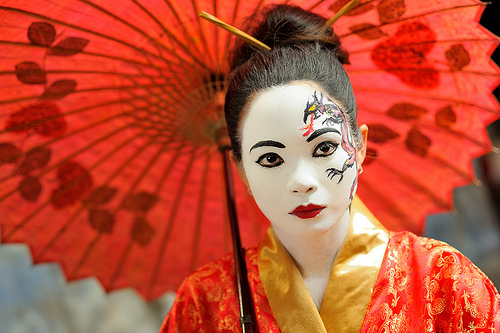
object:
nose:
[283, 152, 318, 199]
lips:
[283, 201, 344, 233]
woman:
[188, 3, 438, 285]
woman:
[159, 3, 499, 331]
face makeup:
[239, 75, 359, 245]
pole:
[221, 159, 250, 321]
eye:
[252, 150, 288, 170]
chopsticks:
[199, 0, 357, 52]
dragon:
[287, 89, 379, 211]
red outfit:
[159, 228, 497, 330]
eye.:
[309, 137, 340, 159]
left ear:
[229, 155, 249, 189]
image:
[298, 88, 360, 201]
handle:
[212, 144, 259, 330]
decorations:
[5, 18, 165, 239]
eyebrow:
[248, 137, 286, 152]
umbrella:
[7, 4, 222, 255]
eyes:
[253, 140, 341, 168]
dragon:
[302, 96, 366, 183]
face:
[239, 79, 357, 233]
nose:
[284, 167, 323, 193]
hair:
[238, 35, 345, 81]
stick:
[195, 10, 274, 51]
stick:
[327, 2, 360, 32]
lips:
[283, 199, 331, 221]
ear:
[354, 123, 375, 172]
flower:
[7, 24, 84, 201]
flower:
[54, 159, 87, 214]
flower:
[373, 22, 443, 95]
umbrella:
[374, 6, 497, 206]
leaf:
[24, 19, 55, 49]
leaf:
[13, 60, 48, 87]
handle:
[218, 148, 257, 332]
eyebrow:
[304, 127, 345, 142]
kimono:
[159, 214, 498, 330]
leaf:
[129, 218, 155, 247]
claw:
[323, 165, 347, 187]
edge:
[433, 88, 499, 229]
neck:
[275, 233, 348, 282]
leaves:
[42, 153, 167, 249]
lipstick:
[286, 201, 328, 220]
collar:
[257, 241, 390, 332]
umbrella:
[2, 5, 484, 296]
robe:
[158, 195, 498, 331]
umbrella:
[0, 0, 499, 330]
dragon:
[303, 91, 360, 199]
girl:
[153, 5, 498, 331]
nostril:
[304, 182, 313, 192]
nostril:
[292, 187, 298, 196]